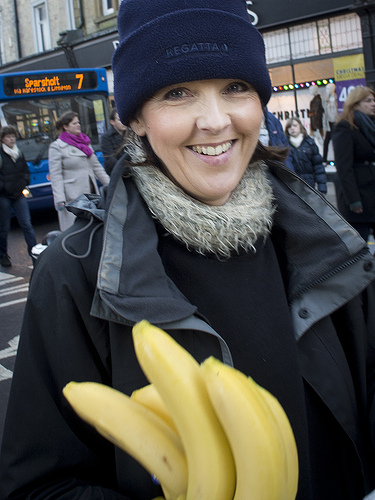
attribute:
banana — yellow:
[62, 319, 298, 500]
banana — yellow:
[58, 377, 187, 499]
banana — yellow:
[197, 357, 288, 499]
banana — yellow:
[131, 316, 236, 500]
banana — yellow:
[249, 377, 304, 498]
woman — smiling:
[1, 1, 374, 498]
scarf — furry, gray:
[128, 132, 273, 255]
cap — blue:
[111, 0, 271, 125]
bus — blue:
[0, 67, 120, 231]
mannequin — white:
[322, 82, 337, 169]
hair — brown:
[331, 85, 374, 130]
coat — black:
[332, 108, 374, 236]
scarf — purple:
[56, 128, 96, 157]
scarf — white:
[4, 142, 21, 163]